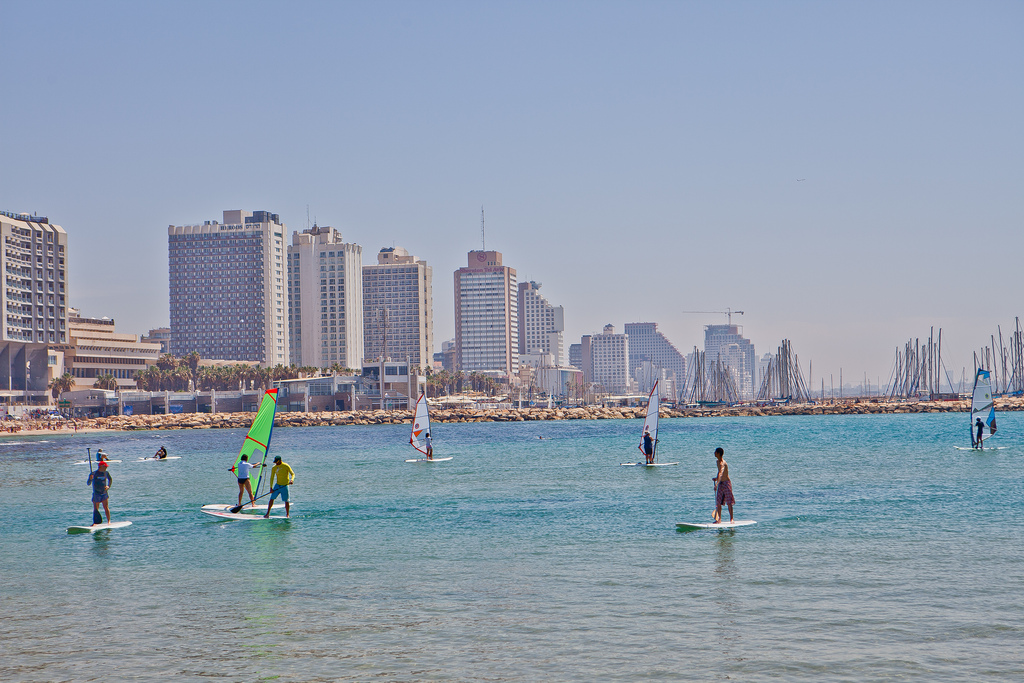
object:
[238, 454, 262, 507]
person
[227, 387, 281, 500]
sailboard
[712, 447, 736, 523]
person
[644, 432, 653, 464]
person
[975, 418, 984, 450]
person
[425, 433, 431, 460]
person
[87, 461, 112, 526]
person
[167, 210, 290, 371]
building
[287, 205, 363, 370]
building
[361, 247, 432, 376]
building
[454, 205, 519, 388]
building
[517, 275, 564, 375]
building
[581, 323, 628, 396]
building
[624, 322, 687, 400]
building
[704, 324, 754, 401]
building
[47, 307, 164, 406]
building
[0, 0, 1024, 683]
picture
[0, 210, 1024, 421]
city